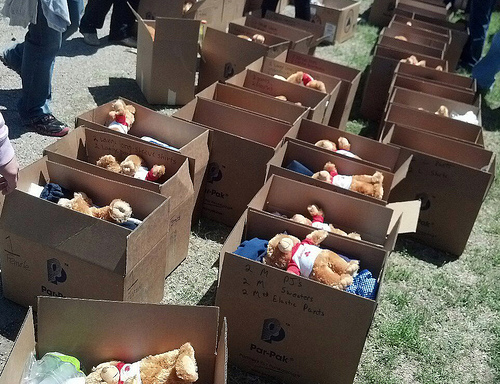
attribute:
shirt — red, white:
[284, 238, 323, 279]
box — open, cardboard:
[220, 226, 398, 356]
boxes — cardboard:
[120, 109, 399, 192]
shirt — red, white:
[281, 242, 334, 278]